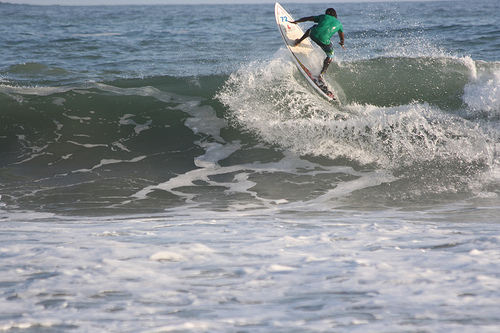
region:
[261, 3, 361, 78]
man is on surfboard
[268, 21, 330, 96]
red and white board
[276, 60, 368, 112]
white wake around man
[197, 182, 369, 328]
white and choppy water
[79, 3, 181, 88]
blue water in distance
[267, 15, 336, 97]
board is crossing wave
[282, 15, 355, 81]
man has black shorts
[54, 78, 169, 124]
wave is turning over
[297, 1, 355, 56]
this is a man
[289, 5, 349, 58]
the man is sea surfing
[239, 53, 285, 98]
the wave is splashy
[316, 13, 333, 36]
this is the t shirt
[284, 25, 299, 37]
the board is white in color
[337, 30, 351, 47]
this is the hand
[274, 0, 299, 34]
the board is big in size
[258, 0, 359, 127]
A person surfing a wave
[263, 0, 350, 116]
A person surfing a wave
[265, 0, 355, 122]
A person surfing a wave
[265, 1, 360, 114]
A person surfing a wave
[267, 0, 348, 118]
A person surfing a wave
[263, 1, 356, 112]
A person surfing a wave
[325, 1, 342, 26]
head of a person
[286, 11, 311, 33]
arm of a person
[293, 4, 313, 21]
an arm of a person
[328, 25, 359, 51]
an arm of a person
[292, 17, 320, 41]
leg of a person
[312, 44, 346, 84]
leg of a person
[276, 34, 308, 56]
feet of a person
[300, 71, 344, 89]
feet of a person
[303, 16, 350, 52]
body of a person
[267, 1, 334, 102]
this is a surf board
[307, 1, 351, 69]
this is a person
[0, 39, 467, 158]
this is a wave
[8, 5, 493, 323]
this is a water obdy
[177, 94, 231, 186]
this is water foam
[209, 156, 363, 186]
this is water foam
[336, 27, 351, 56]
this is a hand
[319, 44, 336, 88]
this is a leg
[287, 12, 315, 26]
this is a hand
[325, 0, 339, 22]
this is a head